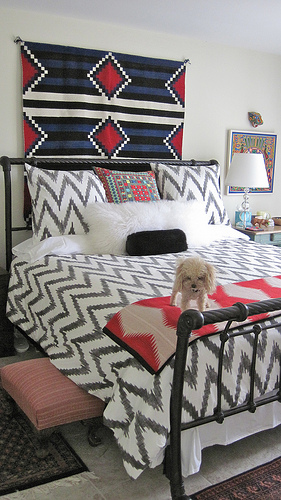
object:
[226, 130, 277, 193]
picture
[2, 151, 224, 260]
headboard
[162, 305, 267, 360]
footboard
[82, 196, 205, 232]
white fabric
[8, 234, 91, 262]
white fabric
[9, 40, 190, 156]
helmet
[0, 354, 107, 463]
bench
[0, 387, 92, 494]
mat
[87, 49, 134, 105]
chevron pattern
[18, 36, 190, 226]
tapestry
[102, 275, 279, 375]
blanket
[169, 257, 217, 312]
animal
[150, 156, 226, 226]
pillow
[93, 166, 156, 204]
pillow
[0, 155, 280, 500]
bed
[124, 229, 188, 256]
pillow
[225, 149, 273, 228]
lamp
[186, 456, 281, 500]
rug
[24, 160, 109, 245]
pillow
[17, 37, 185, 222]
cloth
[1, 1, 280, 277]
wall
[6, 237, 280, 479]
cover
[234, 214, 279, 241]
side table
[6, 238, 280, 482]
blanket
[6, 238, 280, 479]
comforter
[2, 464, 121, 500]
floor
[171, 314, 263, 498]
artwork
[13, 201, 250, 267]
fabric